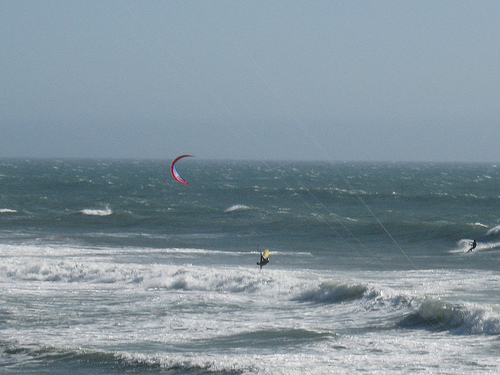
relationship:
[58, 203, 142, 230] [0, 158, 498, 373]
wave in water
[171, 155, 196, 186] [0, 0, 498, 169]
kite in sky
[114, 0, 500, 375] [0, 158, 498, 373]
string extending from water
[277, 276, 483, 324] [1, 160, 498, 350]
waves in water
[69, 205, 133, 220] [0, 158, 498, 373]
wave in water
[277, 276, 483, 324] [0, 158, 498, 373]
waves in water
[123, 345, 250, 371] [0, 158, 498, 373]
waves in water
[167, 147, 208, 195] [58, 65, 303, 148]
kite in sky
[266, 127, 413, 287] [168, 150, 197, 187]
string on kite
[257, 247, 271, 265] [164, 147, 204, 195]
person with kite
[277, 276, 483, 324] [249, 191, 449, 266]
waves in water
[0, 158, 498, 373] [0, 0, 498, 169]
water below sky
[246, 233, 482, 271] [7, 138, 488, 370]
person in water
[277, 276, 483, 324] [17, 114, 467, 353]
waves in water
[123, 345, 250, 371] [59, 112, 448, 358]
waves in water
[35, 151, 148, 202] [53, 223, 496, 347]
white caps on waves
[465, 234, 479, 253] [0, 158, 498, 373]
person skiing in water